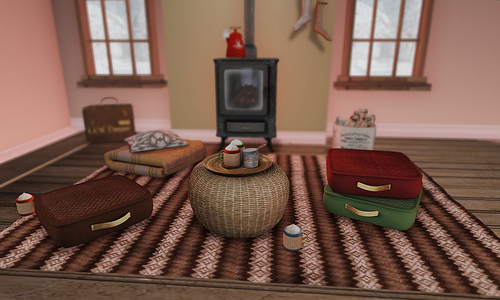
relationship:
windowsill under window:
[335, 70, 432, 85] [350, 1, 416, 70]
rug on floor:
[1, 135, 498, 297] [2, 134, 493, 296]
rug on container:
[1, 135, 498, 297] [324, 184, 423, 229]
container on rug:
[318, 184, 427, 234] [1, 135, 498, 297]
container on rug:
[320, 148, 427, 198] [1, 135, 498, 297]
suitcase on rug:
[30, 175, 155, 249] [1, 135, 498, 297]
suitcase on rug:
[318, 181, 428, 233] [1, 135, 498, 297]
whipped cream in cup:
[283, 223, 304, 239] [274, 209, 321, 256]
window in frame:
[87, 2, 150, 79] [72, 2, 169, 89]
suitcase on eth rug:
[30, 171, 155, 245] [1, 135, 498, 297]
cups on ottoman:
[222, 137, 264, 171] [185, 150, 291, 238]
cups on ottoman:
[282, 220, 305, 251] [185, 150, 291, 238]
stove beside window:
[163, 35, 313, 143] [333, 0, 436, 97]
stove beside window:
[163, 35, 313, 143] [69, 0, 169, 90]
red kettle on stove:
[220, 22, 247, 59] [209, 2, 284, 149]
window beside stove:
[87, 2, 150, 79] [214, 1, 279, 152]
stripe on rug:
[0, 157, 500, 296] [1, 135, 498, 297]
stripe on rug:
[187, 235, 223, 277] [1, 135, 498, 297]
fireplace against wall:
[214, 59, 282, 138] [62, 7, 480, 156]